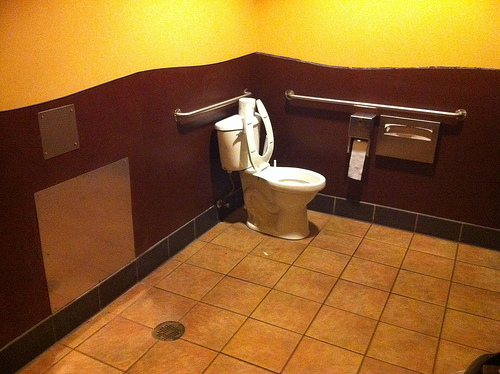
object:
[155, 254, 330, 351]
floor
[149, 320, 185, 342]
drain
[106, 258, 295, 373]
ground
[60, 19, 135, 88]
wall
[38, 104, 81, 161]
plate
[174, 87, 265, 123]
bar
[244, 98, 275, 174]
seat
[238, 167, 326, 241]
closet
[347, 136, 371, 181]
paper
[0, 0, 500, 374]
bathroom